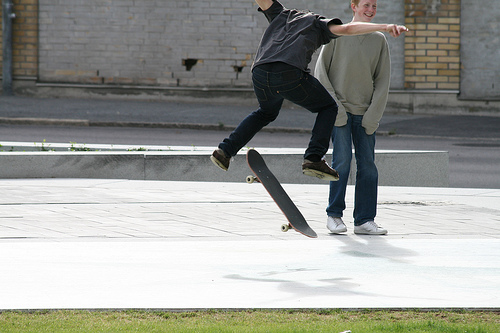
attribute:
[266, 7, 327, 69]
boy — skateboarding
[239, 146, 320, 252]
skateboard — black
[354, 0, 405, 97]
other boy — standing, grinning, smiling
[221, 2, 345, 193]
skateboarder — performing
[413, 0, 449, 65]
wall — brick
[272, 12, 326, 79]
shirt — grey, black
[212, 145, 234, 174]
shoe — black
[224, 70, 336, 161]
jeans — blue, black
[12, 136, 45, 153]
marking — white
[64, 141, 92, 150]
grass — green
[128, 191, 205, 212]
sidewalk — concrete, white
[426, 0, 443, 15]
brick — missing, tan, tank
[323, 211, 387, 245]
shoes — white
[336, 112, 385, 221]
jeans — blue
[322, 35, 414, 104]
sweater — grey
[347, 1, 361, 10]
hair — short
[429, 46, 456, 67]
brick — tan